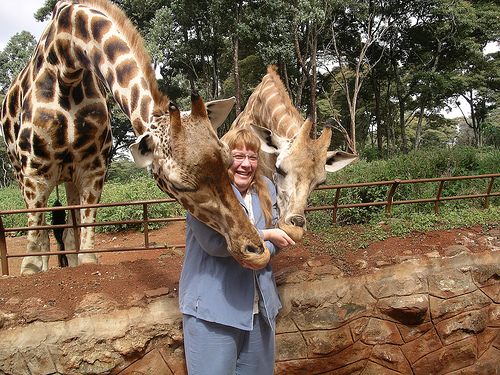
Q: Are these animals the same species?
A: Yes, all the animals are giraffes.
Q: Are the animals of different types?
A: No, all the animals are giraffes.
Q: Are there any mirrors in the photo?
A: No, there are no mirrors.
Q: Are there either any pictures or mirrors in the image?
A: No, there are no mirrors or pictures.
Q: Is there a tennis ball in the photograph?
A: No, there are no tennis balls.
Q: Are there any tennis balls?
A: No, there are no tennis balls.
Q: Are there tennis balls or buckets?
A: No, there are no tennis balls or buckets.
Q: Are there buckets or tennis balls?
A: No, there are no tennis balls or buckets.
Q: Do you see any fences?
A: Yes, there is a fence.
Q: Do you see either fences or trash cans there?
A: Yes, there is a fence.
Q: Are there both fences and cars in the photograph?
A: No, there is a fence but no cars.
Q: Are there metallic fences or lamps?
A: Yes, there is a metal fence.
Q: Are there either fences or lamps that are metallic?
A: Yes, the fence is metallic.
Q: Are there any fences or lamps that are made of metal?
A: Yes, the fence is made of metal.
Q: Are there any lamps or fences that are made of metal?
A: Yes, the fence is made of metal.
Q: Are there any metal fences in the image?
A: Yes, there is a metal fence.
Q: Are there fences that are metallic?
A: Yes, there is a fence that is metallic.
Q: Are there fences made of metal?
A: Yes, there is a fence that is made of metal.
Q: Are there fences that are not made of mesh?
A: Yes, there is a fence that is made of metal.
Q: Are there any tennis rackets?
A: No, there are no tennis rackets.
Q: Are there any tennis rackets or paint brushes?
A: No, there are no tennis rackets or paint brushes.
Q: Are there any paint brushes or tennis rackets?
A: No, there are no tennis rackets or paint brushes.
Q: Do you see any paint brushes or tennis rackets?
A: No, there are no tennis rackets or paint brushes.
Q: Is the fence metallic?
A: Yes, the fence is metallic.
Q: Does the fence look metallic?
A: Yes, the fence is metallic.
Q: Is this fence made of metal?
A: Yes, the fence is made of metal.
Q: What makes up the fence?
A: The fence is made of metal.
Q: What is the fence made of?
A: The fence is made of metal.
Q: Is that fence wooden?
A: No, the fence is metallic.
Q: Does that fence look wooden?
A: No, the fence is metallic.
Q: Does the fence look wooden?
A: No, the fence is metallic.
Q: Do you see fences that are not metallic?
A: No, there is a fence but it is metallic.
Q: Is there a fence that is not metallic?
A: No, there is a fence but it is metallic.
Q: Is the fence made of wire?
A: No, the fence is made of metal.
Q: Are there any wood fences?
A: No, there is a fence but it is made of metal.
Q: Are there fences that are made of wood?
A: No, there is a fence but it is made of metal.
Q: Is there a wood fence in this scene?
A: No, there is a fence but it is made of metal.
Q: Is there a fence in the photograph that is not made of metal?
A: No, there is a fence but it is made of metal.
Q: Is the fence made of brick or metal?
A: The fence is made of metal.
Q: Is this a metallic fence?
A: Yes, this is a metallic fence.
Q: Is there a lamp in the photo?
A: No, there are no lamps.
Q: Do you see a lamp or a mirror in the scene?
A: No, there are no lamps or mirrors.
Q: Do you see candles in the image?
A: No, there are no candles.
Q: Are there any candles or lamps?
A: No, there are no candles or lamps.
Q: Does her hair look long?
A: Yes, the hair is long.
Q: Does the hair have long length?
A: Yes, the hair is long.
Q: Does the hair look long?
A: Yes, the hair is long.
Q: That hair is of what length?
A: The hair is long.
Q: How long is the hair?
A: The hair is long.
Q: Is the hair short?
A: No, the hair is long.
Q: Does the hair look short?
A: No, the hair is long.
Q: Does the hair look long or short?
A: The hair is long.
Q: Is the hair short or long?
A: The hair is long.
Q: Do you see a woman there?
A: Yes, there is a woman.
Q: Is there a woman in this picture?
A: Yes, there is a woman.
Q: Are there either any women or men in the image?
A: Yes, there is a woman.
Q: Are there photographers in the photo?
A: No, there are no photographers.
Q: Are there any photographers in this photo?
A: No, there are no photographers.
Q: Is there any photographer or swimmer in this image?
A: No, there are no photographers or swimmers.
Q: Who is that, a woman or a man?
A: That is a woman.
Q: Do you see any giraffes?
A: Yes, there is a giraffe.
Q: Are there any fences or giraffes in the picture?
A: Yes, there is a giraffe.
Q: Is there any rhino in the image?
A: No, there are no rhinos.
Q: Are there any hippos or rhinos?
A: No, there are no rhinos or hippos.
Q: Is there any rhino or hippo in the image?
A: No, there are no rhinos or hippos.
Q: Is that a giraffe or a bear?
A: That is a giraffe.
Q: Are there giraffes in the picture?
A: Yes, there is a giraffe.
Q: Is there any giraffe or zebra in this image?
A: Yes, there is a giraffe.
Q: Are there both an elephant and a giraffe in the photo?
A: No, there is a giraffe but no elephants.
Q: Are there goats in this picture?
A: No, there are no goats.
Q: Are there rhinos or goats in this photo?
A: No, there are no goats or rhinos.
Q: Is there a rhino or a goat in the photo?
A: No, there are no goats or rhinos.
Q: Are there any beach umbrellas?
A: No, there are no beach umbrellas.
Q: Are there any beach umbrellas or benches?
A: No, there are no beach umbrellas or benches.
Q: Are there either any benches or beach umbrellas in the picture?
A: No, there are no beach umbrellas or benches.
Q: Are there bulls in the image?
A: No, there are no bulls.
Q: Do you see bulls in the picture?
A: No, there are no bulls.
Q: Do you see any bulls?
A: No, there are no bulls.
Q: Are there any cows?
A: No, there are no cows.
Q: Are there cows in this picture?
A: No, there are no cows.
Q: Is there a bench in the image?
A: No, there are no benches.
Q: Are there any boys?
A: No, there are no boys.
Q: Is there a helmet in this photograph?
A: No, there are no helmets.